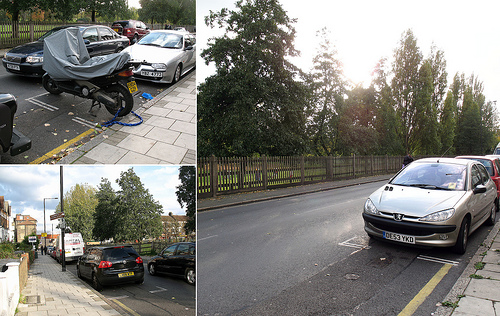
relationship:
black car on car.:
[1, 23, 130, 77] [119, 30, 196, 83]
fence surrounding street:
[196, 153, 403, 199] [202, 164, 468, 314]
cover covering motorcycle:
[38, 22, 124, 79] [31, 20, 138, 117]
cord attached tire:
[108, 102, 165, 154] [137, 85, 157, 101]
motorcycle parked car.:
[37, 30, 137, 113] [121, 30, 193, 75]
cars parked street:
[70, 216, 160, 281] [224, 232, 295, 276]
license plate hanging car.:
[383, 230, 416, 244] [325, 114, 499, 270]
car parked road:
[356, 153, 485, 250] [223, 227, 334, 293]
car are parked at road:
[356, 153, 485, 250] [199, 174, 497, 313]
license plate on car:
[383, 230, 416, 244] [354, 142, 499, 262]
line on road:
[399, 258, 453, 313] [206, 177, 356, 314]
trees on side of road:
[204, 9, 499, 149] [204, 185, 419, 312]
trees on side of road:
[62, 167, 195, 238] [60, 232, 194, 314]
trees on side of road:
[5, 0, 195, 32] [5, 20, 190, 132]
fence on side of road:
[247, 153, 327, 181] [251, 215, 328, 275]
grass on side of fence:
[194, 160, 376, 196] [196, 149, 416, 195]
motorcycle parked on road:
[42, 25, 139, 117] [9, 35, 159, 146]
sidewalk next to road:
[9, 239, 130, 313] [69, 248, 189, 313]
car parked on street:
[356, 153, 485, 250] [201, 177, 480, 304]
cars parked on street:
[76, 245, 144, 291] [201, 177, 480, 304]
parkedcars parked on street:
[148, 242, 196, 284] [9, 47, 166, 145]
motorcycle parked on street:
[42, 25, 139, 117] [55, 250, 195, 315]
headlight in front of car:
[420, 205, 455, 225] [356, 153, 485, 250]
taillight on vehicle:
[130, 255, 143, 265] [74, 237, 147, 292]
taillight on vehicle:
[94, 257, 112, 270] [74, 237, 147, 292]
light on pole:
[52, 194, 59, 202] [40, 192, 60, 234]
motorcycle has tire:
[42, 25, 139, 117] [104, 84, 134, 117]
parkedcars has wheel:
[148, 242, 196, 284] [142, 261, 157, 274]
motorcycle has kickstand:
[42, 25, 139, 117] [90, 99, 100, 109]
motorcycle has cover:
[42, 25, 139, 117] [38, 30, 122, 82]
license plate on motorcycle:
[383, 230, 416, 244] [30, 18, 150, 135]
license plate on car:
[382, 227, 420, 245] [314, 110, 499, 302]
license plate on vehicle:
[383, 230, 416, 244] [366, 149, 491, 253]